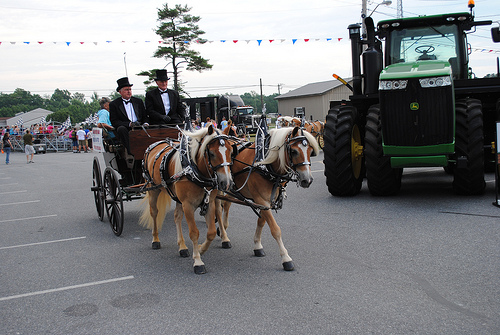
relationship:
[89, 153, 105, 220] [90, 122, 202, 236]
wheel on brown carriage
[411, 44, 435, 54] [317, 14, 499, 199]
steering wheel of tractor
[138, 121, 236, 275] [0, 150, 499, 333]
horse on pavement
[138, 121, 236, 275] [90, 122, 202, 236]
horse pulling brown carriage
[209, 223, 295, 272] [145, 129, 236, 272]
hooves of horse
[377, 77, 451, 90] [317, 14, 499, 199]
head lights front of tractor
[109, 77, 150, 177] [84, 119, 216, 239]
man on wagon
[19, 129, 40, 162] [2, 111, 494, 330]
people in parking lot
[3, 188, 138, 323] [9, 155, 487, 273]
lines on pavement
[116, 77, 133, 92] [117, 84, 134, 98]
hat on head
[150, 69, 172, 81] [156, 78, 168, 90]
hat on head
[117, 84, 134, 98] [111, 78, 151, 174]
head of man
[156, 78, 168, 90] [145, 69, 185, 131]
head of man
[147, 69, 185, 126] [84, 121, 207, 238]
man riding carriage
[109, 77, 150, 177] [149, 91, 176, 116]
man wearing suits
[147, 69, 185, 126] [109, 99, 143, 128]
man wearing suits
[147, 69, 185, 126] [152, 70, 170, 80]
man wearing hat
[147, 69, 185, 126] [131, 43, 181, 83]
man wearing hat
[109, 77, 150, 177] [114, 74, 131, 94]
man wearing hat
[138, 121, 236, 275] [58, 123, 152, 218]
horse driving carriage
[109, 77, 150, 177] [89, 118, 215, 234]
man driving carriage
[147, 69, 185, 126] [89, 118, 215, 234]
man driving carriage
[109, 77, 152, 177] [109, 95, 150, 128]
man wearing suits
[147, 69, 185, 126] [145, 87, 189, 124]
man wearing suits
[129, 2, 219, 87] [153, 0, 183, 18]
tree with leaves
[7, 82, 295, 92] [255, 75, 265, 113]
power lines on pole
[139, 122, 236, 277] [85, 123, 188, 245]
horse pulling buggy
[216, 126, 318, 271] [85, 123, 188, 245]
horse pulling buggy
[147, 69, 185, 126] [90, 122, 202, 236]
man on brown carriage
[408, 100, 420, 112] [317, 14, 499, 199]
logo on tractor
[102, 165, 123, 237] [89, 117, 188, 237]
large wheels on buggy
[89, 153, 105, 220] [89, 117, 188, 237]
wheel on buggy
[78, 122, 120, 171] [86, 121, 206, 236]
sign on side of buggy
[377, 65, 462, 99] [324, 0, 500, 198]
headlights in front of tractor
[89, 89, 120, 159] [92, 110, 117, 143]
man wearing shirt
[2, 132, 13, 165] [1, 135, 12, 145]
people wearing shirt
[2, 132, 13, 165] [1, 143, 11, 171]
people wearing pants